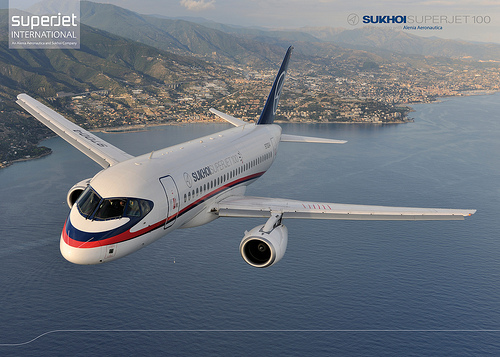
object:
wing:
[14, 90, 136, 168]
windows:
[183, 151, 273, 203]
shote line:
[95, 115, 215, 133]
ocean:
[0, 90, 499, 356]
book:
[158, 175, 180, 229]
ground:
[443, 130, 470, 165]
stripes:
[62, 169, 266, 250]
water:
[1, 92, 499, 356]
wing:
[214, 195, 477, 222]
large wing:
[14, 93, 131, 169]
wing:
[209, 107, 247, 127]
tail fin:
[256, 44, 294, 126]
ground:
[338, 134, 368, 194]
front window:
[76, 186, 154, 221]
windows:
[70, 184, 152, 222]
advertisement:
[5, 2, 496, 53]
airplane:
[14, 44, 476, 268]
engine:
[239, 222, 288, 268]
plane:
[15, 45, 477, 268]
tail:
[258, 45, 295, 124]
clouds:
[99, 0, 500, 44]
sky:
[101, 0, 499, 47]